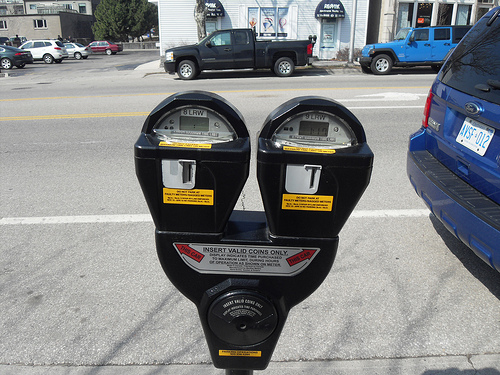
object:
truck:
[162, 28, 318, 81]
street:
[0, 77, 493, 359]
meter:
[132, 89, 376, 375]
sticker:
[158, 141, 213, 150]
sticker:
[282, 145, 336, 154]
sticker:
[162, 187, 214, 206]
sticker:
[281, 193, 334, 212]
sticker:
[169, 241, 322, 278]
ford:
[403, 2, 499, 275]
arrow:
[337, 91, 431, 111]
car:
[357, 25, 472, 76]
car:
[0, 45, 33, 70]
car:
[61, 41, 92, 61]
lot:
[1, 41, 159, 76]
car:
[18, 38, 65, 65]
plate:
[455, 116, 495, 157]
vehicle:
[85, 40, 125, 56]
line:
[1, 111, 153, 121]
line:
[0, 208, 432, 226]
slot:
[178, 159, 194, 186]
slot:
[303, 164, 323, 193]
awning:
[202, 0, 225, 18]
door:
[201, 18, 226, 45]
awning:
[314, 0, 347, 22]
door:
[318, 18, 341, 60]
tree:
[93, 0, 159, 43]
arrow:
[174, 242, 205, 263]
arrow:
[285, 248, 319, 267]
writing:
[164, 191, 212, 205]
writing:
[284, 196, 332, 209]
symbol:
[464, 101, 482, 116]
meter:
[132, 88, 256, 237]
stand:
[154, 235, 341, 374]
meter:
[254, 93, 376, 246]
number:
[480, 134, 491, 149]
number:
[475, 131, 484, 145]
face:
[152, 104, 239, 146]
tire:
[177, 59, 201, 81]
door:
[405, 39, 433, 63]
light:
[306, 44, 312, 56]